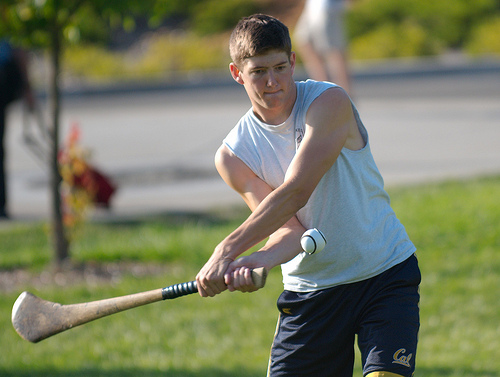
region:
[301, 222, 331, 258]
white with black stripes ball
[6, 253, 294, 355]
wooden bat looking stick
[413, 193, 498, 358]
field of green grass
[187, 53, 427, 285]
tee wearing a white tank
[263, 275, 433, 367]
teen wearing blue shorts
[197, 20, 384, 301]
teen looking at ball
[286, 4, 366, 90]
person's legs behind boy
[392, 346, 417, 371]
boy's shorts with logo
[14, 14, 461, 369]
boy holding playing equipment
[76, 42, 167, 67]
green vegetation in background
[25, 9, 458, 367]
The man is playing ball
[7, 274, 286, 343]
The bat is brown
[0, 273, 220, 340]
The bat is made of wood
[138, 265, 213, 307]
The bat has a blue grip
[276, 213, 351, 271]
The ball is about to be hit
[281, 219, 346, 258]
The ball is white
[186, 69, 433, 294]
The man is wearing a white shirt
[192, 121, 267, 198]
The man's shirt is sleeveless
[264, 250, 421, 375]
The man is wearing blue shorts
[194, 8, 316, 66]
The man has dark hair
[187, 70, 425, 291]
THE BOYS SHIRT IS GREY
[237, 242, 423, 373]
THE BOYS SHORTS ARE BLUE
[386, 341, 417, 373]
THE BOYS SHORTS SAY CAL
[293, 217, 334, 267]
THE BALL IS WHITE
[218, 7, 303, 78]
THE BOYS HAIR IS SHORT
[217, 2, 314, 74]
THE BOY'S HAIR IS BROWN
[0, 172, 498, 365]
THE GRASS IS GREEN AND LUSH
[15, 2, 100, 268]
THE TREE IS BEHIND THE BOY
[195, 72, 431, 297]
THE BOY'S SHIRT IS SLEEVELESS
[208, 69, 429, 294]
THE BOY'S SHIRT IS COTTON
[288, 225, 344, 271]
a white, small ball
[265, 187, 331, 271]
a white, small ball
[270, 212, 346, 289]
a white, small ball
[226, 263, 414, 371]
the short is blue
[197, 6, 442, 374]
this is a person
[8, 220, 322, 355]
the person has a bat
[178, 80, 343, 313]
the hand of a man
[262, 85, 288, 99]
the mouth of a man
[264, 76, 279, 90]
the nose of a man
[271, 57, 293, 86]
the eye of a man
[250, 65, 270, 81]
the eye of a man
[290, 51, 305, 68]
the ear of a man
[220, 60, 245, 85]
the ear of a man